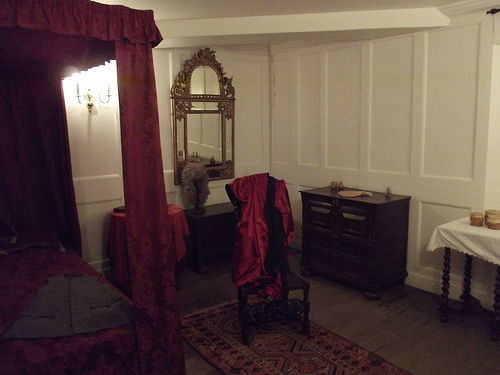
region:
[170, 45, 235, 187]
antique mirror hanging on wal in bedroom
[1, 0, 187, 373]
canopy bed with mauve curtains and matcing spread and pillows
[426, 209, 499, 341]
table with turned legs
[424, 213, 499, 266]
white linen tablecloth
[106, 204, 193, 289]
table cloth that matches bed dressings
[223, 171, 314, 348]
old fashionedchair sitting in the middle of the floor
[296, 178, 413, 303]
dark wood cabinet with drawers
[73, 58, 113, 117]
candlestick-like lights on the wall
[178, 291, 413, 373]
area rug in same color as bed and table cloth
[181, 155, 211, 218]
decorative object on the long table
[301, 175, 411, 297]
a dresser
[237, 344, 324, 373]
a rug on the floor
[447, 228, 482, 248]
a table cloth on the table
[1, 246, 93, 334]
a bed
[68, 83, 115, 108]
lights on the wall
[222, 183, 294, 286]
clothing on the chair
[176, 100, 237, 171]
the mirror on the wall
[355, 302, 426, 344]
the wooden floor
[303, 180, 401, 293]
the dresser is brown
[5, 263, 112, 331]
a comforter on the bed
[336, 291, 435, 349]
the floor is made of wood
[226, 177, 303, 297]
the clothe is red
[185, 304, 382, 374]
the carpet is on the ground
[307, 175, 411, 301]
the cabinet is wooden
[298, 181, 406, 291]
the cabinet is brown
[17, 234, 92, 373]
the bedsheet is purple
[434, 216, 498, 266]
the table clothe is white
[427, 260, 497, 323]
the table legs are brown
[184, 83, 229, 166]
mirror is on the wall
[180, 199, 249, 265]
the cabinet is brown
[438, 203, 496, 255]
Small table in the corner.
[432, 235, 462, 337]
Brown stick on the table.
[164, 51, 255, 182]
Gold mirror on the wall.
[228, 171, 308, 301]
Red sheet on top of chair.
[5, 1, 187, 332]
Red canopy over bed.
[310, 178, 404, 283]
Brown dresser against the wall.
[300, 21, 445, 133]
Plane white wall on the corner.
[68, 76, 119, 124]
Light fixture on the wall.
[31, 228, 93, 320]
Mattress on top of bed.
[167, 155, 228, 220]
Wig on top of dresser.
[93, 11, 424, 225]
a mirror on the wall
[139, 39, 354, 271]
a gold mirror on the wall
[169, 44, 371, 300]
a mirror framed in gold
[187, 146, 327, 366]
a chiar in side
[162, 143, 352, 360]
a brown chair inside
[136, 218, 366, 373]
a rug on the floor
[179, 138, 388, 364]
a chair on the rug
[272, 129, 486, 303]
a brown dresser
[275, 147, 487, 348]
a small dresser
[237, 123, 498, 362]
a small brown dresser